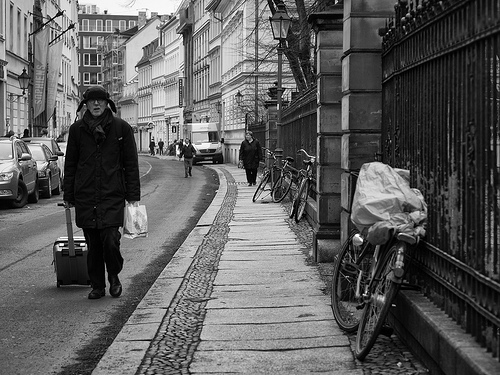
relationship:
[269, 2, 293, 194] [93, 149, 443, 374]
light on sidewalk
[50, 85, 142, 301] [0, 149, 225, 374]
man in street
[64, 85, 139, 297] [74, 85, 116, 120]
man wearing hat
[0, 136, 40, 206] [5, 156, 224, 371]
car parked on road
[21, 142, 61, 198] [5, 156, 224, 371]
car parked on road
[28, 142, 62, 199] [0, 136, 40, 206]
car parked on car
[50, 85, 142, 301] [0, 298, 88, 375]
man walking in road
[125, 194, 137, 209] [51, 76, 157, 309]
hand of a man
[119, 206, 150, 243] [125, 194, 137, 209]
bag in hand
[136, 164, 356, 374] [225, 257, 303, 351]
sidewalk made of tiles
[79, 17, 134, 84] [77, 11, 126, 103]
windows on building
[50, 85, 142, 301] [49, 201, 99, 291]
man pulling luggage